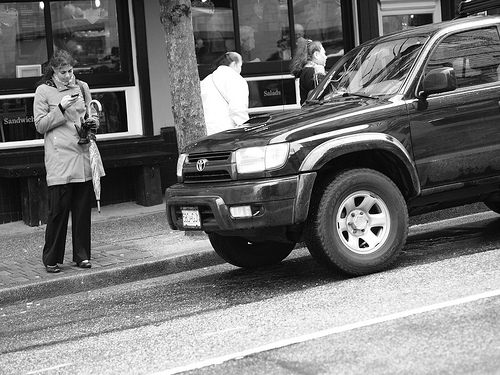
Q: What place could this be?
A: It is a street.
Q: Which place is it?
A: It is a street.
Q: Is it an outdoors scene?
A: Yes, it is outdoors.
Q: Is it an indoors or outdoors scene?
A: It is outdoors.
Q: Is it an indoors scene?
A: No, it is outdoors.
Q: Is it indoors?
A: No, it is outdoors.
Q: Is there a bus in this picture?
A: No, there are no buses.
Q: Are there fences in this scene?
A: No, there are no fences.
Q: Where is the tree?
A: The tree is on the sidewalk.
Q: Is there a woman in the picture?
A: Yes, there is a woman.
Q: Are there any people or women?
A: Yes, there is a woman.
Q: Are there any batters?
A: No, there are no batters.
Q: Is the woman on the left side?
A: Yes, the woman is on the left of the image.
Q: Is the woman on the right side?
A: No, the woman is on the left of the image.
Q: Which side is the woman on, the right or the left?
A: The woman is on the left of the image.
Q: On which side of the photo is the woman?
A: The woman is on the left of the image.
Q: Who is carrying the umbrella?
A: The woman is carrying the umbrella.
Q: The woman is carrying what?
A: The woman is carrying an umbrella.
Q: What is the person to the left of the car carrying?
A: The woman is carrying an umbrella.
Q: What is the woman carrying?
A: The woman is carrying an umbrella.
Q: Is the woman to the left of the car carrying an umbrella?
A: Yes, the woman is carrying an umbrella.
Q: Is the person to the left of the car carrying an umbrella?
A: Yes, the woman is carrying an umbrella.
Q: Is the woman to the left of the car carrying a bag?
A: No, the woman is carrying an umbrella.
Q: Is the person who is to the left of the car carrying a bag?
A: No, the woman is carrying an umbrella.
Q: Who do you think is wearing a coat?
A: The woman is wearing a coat.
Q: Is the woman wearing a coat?
A: Yes, the woman is wearing a coat.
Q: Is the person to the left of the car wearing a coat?
A: Yes, the woman is wearing a coat.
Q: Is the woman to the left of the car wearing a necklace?
A: No, the woman is wearing a coat.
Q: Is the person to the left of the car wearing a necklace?
A: No, the woman is wearing a coat.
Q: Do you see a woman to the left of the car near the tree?
A: Yes, there is a woman to the left of the car.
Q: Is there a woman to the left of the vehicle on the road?
A: Yes, there is a woman to the left of the car.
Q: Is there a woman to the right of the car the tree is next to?
A: No, the woman is to the left of the car.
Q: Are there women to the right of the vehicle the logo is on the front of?
A: No, the woman is to the left of the car.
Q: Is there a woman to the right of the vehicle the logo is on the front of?
A: No, the woman is to the left of the car.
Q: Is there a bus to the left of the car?
A: No, there is a woman to the left of the car.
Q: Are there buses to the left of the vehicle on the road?
A: No, there is a woman to the left of the car.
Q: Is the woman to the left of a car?
A: Yes, the woman is to the left of a car.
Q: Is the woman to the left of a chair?
A: No, the woman is to the left of a car.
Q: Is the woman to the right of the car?
A: No, the woman is to the left of the car.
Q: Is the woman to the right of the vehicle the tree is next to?
A: No, the woman is to the left of the car.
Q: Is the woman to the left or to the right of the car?
A: The woman is to the left of the car.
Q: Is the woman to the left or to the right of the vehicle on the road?
A: The woman is to the left of the car.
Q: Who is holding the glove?
A: The woman is holding the glove.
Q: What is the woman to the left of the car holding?
A: The woman is holding the glove.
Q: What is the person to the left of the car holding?
A: The woman is holding the glove.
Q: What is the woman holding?
A: The woman is holding the glove.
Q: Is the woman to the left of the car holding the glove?
A: Yes, the woman is holding the glove.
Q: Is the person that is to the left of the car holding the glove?
A: Yes, the woman is holding the glove.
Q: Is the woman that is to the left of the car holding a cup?
A: No, the woman is holding the glove.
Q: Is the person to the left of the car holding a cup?
A: No, the woman is holding the glove.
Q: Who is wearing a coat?
A: The woman is wearing a coat.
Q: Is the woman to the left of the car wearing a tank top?
A: No, the woman is wearing a coat.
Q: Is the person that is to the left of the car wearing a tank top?
A: No, the woman is wearing a coat.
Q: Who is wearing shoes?
A: The woman is wearing shoes.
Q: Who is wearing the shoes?
A: The woman is wearing shoes.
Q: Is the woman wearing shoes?
A: Yes, the woman is wearing shoes.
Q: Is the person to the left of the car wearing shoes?
A: Yes, the woman is wearing shoes.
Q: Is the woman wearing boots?
A: No, the woman is wearing shoes.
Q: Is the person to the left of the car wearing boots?
A: No, the woman is wearing shoes.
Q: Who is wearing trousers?
A: The woman is wearing trousers.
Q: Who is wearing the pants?
A: The woman is wearing trousers.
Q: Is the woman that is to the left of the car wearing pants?
A: Yes, the woman is wearing pants.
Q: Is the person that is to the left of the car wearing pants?
A: Yes, the woman is wearing pants.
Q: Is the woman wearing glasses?
A: No, the woman is wearing pants.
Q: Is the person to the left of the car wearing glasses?
A: No, the woman is wearing pants.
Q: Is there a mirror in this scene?
A: Yes, there is a mirror.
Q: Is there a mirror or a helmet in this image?
A: Yes, there is a mirror.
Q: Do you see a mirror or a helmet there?
A: Yes, there is a mirror.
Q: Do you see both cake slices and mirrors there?
A: No, there is a mirror but no cake slices.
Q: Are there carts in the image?
A: No, there are no carts.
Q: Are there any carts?
A: No, there are no carts.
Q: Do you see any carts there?
A: No, there are no carts.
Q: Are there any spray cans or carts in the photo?
A: No, there are no carts or spray cans.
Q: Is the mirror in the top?
A: Yes, the mirror is in the top of the image.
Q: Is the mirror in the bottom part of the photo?
A: No, the mirror is in the top of the image.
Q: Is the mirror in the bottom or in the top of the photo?
A: The mirror is in the top of the image.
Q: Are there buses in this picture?
A: No, there are no buses.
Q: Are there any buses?
A: No, there are no buses.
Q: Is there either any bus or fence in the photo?
A: No, there are no buses or fences.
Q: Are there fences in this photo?
A: No, there are no fences.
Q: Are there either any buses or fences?
A: No, there are no fences or buses.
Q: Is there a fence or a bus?
A: No, there are no fences or buses.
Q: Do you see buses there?
A: No, there are no buses.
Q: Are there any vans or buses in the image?
A: No, there are no buses or vans.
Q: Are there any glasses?
A: No, there are no glasses.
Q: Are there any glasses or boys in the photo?
A: No, there are no glasses or boys.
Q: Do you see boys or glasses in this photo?
A: No, there are no glasses or boys.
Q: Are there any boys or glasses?
A: No, there are no glasses or boys.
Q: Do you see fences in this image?
A: No, there are no fences.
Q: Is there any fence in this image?
A: No, there are no fences.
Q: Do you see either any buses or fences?
A: No, there are no fences or buses.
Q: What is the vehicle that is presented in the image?
A: The vehicle is a car.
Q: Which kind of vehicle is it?
A: The vehicle is a car.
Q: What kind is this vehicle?
A: That is a car.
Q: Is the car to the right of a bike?
A: No, the car is to the right of the cell phone.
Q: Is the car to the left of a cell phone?
A: No, the car is to the right of a cell phone.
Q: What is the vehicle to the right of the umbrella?
A: The vehicle is a car.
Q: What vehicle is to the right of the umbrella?
A: The vehicle is a car.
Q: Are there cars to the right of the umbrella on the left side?
A: Yes, there is a car to the right of the umbrella.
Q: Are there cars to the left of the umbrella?
A: No, the car is to the right of the umbrella.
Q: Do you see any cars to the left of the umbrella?
A: No, the car is to the right of the umbrella.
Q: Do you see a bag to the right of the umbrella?
A: No, there is a car to the right of the umbrella.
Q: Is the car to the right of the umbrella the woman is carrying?
A: Yes, the car is to the right of the umbrella.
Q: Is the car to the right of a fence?
A: No, the car is to the right of the umbrella.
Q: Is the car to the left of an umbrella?
A: No, the car is to the right of an umbrella.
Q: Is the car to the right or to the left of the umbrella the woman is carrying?
A: The car is to the right of the umbrella.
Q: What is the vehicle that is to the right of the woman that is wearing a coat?
A: The vehicle is a car.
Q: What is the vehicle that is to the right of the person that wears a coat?
A: The vehicle is a car.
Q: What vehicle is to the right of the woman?
A: The vehicle is a car.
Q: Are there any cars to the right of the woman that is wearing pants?
A: Yes, there is a car to the right of the woman.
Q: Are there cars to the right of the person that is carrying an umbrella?
A: Yes, there is a car to the right of the woman.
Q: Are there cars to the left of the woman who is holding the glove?
A: No, the car is to the right of the woman.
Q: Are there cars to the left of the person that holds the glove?
A: No, the car is to the right of the woman.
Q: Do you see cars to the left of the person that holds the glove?
A: No, the car is to the right of the woman.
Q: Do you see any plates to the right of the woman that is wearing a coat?
A: No, there is a car to the right of the woman.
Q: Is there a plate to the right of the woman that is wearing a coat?
A: No, there is a car to the right of the woman.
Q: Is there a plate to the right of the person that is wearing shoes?
A: No, there is a car to the right of the woman.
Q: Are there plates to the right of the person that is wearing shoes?
A: No, there is a car to the right of the woman.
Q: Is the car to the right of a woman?
A: Yes, the car is to the right of a woman.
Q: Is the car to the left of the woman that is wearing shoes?
A: No, the car is to the right of the woman.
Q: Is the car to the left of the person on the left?
A: No, the car is to the right of the woman.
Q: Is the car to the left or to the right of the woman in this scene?
A: The car is to the right of the woman.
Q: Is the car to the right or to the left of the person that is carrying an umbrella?
A: The car is to the right of the woman.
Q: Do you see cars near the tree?
A: Yes, there is a car near the tree.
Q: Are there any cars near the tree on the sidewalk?
A: Yes, there is a car near the tree.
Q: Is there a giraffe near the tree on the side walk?
A: No, there is a car near the tree.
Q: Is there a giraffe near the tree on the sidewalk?
A: No, there is a car near the tree.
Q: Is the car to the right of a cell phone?
A: Yes, the car is to the right of a cell phone.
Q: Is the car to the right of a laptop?
A: No, the car is to the right of a cell phone.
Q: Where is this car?
A: The car is on the road.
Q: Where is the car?
A: The car is on the road.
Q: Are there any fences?
A: No, there are no fences.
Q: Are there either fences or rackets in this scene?
A: No, there are no fences or rackets.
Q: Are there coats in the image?
A: Yes, there is a coat.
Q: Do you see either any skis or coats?
A: Yes, there is a coat.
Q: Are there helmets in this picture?
A: No, there are no helmets.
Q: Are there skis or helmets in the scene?
A: No, there are no helmets or skis.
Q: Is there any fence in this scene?
A: No, there are no fences.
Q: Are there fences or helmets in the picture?
A: No, there are no fences or helmets.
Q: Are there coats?
A: Yes, there is a coat.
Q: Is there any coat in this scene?
A: Yes, there is a coat.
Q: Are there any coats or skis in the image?
A: Yes, there is a coat.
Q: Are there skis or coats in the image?
A: Yes, there is a coat.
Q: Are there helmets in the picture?
A: No, there are no helmets.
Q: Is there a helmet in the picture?
A: No, there are no helmets.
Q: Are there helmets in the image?
A: No, there are no helmets.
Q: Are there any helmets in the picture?
A: No, there are no helmets.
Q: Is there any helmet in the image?
A: No, there are no helmets.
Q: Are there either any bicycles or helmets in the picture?
A: No, there are no helmets or bicycles.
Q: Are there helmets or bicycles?
A: No, there are no helmets or bicycles.